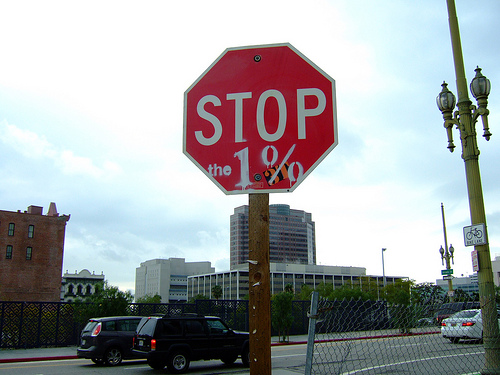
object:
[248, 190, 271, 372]
post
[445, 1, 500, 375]
pole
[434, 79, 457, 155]
lamps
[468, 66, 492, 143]
lamps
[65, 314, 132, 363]
suv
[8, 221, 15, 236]
window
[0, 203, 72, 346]
building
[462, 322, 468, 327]
light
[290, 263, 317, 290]
bricks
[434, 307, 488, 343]
car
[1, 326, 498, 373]
road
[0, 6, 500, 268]
sky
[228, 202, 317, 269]
building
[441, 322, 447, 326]
lights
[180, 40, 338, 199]
sign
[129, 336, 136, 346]
light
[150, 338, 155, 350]
light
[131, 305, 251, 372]
jeep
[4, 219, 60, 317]
wall